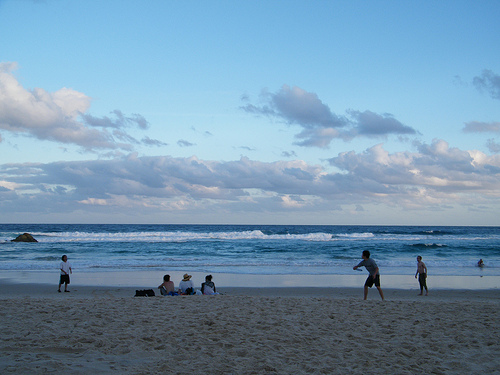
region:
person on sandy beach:
[58, 248, 73, 302]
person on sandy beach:
[159, 269, 174, 299]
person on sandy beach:
[178, 269, 198, 302]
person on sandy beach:
[195, 272, 216, 297]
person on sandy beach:
[408, 254, 429, 294]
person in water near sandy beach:
[473, 254, 488, 270]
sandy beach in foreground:
[28, 291, 493, 373]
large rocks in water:
[9, 231, 42, 248]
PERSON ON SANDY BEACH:
[56, 255, 71, 295]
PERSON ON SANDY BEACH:
[155, 259, 175, 313]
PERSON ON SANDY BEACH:
[178, 266, 195, 296]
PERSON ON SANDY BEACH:
[199, 262, 222, 297]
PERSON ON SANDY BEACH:
[351, 245, 383, 294]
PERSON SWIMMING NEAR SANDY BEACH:
[475, 249, 494, 274]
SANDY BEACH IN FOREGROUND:
[34, 306, 447, 371]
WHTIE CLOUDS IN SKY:
[231, 142, 365, 194]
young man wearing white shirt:
[57, 254, 74, 294]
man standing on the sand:
[412, 255, 429, 297]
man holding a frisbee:
[352, 246, 389, 303]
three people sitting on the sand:
[155, 271, 217, 296]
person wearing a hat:
[177, 266, 193, 296]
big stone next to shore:
[6, 230, 43, 243]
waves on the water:
[4, 226, 499, 243]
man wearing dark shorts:
[350, 248, 385, 300]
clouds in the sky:
[0, 62, 499, 212]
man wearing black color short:
[60, 275, 70, 283]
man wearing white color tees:
[62, 263, 69, 275]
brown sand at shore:
[237, 296, 359, 366]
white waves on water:
[133, 230, 261, 240]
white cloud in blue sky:
[268, 87, 352, 138]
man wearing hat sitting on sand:
[183, 272, 190, 280]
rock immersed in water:
[13, 232, 38, 242]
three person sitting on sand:
[158, 272, 217, 295]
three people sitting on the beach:
[159, 273, 215, 295]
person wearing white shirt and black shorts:
[55, 254, 72, 290]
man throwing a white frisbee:
[351, 248, 385, 298]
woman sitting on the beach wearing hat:
[178, 273, 194, 291]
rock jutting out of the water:
[10, 230, 33, 242]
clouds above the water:
[8, 65, 499, 227]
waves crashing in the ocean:
[37, 228, 374, 245]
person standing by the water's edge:
[410, 253, 433, 300]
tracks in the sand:
[5, 291, 476, 374]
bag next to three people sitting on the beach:
[128, 283, 153, 298]